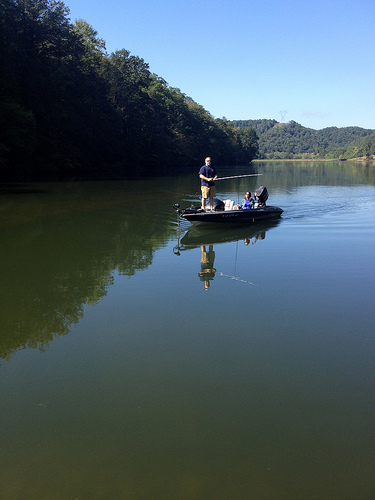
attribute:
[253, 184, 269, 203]
trolling motor — electric, gas powered, small, black, lifted up, outboard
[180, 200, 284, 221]
boat — black, for fishing, small, white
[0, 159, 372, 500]
water — murky, calm, green, big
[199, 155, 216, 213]
man — fishing, trying to fish, enjoying day off, enjoying day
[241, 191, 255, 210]
woman — fishing, trying to fish, enjoying day off, enjoying day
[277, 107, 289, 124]
utility pole — large, metal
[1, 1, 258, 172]
trees — leaf covered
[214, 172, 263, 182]
fishing pole — white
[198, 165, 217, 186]
shirt — blue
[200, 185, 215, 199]
shorts — tan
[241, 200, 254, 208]
shirt — blue